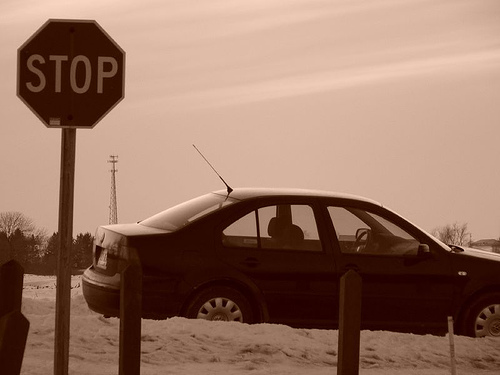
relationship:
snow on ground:
[0, 269, 500, 375] [13, 272, 497, 371]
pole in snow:
[338, 266, 364, 373] [19, 268, 494, 373]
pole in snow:
[116, 258, 146, 373] [19, 268, 494, 373]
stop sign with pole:
[15, 17, 126, 131] [49, 127, 78, 372]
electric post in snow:
[107, 151, 128, 226] [19, 268, 494, 373]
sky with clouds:
[2, 2, 497, 242] [4, 5, 498, 105]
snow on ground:
[25, 305, 499, 372] [13, 272, 497, 371]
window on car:
[223, 200, 322, 250] [85, 187, 498, 339]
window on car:
[327, 204, 429, 256] [85, 187, 498, 339]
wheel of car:
[185, 280, 258, 335] [85, 187, 498, 339]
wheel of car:
[458, 290, 498, 336] [46, 165, 475, 327]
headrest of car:
[265, 212, 287, 238] [110, 172, 498, 349]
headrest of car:
[287, 222, 305, 244] [93, 195, 480, 337]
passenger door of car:
[318, 202, 432, 325] [85, 187, 498, 339]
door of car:
[218, 200, 344, 332] [85, 187, 498, 339]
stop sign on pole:
[15, 17, 126, 131] [53, 127, 75, 373]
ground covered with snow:
[13, 272, 497, 371] [25, 305, 499, 372]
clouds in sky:
[106, 7, 491, 125] [223, 38, 405, 150]